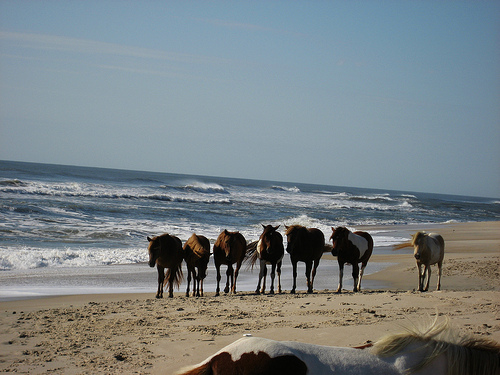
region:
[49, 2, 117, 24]
this is the sky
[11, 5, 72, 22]
the sky is blue in color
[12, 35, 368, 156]
the sky has some clouds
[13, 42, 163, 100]
the clouds are white in color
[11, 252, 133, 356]
this is the beach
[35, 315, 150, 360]
the beach is sandy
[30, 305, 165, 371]
the sand has some tracks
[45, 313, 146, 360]
the sand is brown in color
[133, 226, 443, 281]
these are some horses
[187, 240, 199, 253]
the fur is brown in color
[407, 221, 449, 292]
This is an animal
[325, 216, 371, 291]
This is an animal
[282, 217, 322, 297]
This is an animal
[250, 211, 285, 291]
This is an animal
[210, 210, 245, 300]
This is an animal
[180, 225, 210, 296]
This is an animal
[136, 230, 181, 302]
This is an animal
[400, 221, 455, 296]
These are animals walking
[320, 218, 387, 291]
These are animals walking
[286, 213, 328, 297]
These are animals walking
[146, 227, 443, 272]
seven horses walking on the sand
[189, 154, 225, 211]
waves in the ocean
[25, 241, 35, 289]
waves coming ashore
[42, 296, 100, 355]
prints in the sand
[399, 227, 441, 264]
horses tail is swaying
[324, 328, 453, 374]
horse in front of the other horses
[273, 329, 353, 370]
horse is brown and white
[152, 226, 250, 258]
horses are brown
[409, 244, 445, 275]
horse is a tannish grey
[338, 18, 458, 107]
sky is a clear blue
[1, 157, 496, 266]
a body of water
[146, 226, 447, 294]
a line of horses on beach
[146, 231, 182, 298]
a standing brown horse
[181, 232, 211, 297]
a standing brown horse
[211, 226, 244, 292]
a standing brown horse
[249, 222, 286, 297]
a standing brown horse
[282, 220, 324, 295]
a standing brown horse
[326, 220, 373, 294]
a standing brown and white horse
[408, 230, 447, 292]
a standing brown and white horse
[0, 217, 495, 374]
a light brown sandy beach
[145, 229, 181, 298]
a dark brown horse on the sand at the beach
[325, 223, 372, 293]
a white and brown horse on the sand at the beach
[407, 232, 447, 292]
a beige horse on the sand at the beach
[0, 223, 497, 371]
a sandy beach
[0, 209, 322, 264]
sea foam in the ocean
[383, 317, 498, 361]
a blonde horse mane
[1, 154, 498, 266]
the ocean in the distance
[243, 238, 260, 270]
a swinging horse tain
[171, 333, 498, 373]
a white horse with a brown spot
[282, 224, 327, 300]
a dark brown horse on the sand at the beach